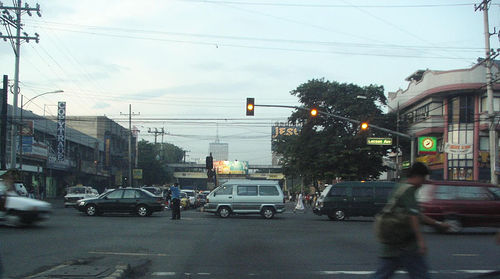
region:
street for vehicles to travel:
[22, 218, 492, 260]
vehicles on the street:
[60, 172, 499, 227]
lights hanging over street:
[238, 92, 379, 135]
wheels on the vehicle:
[87, 202, 153, 219]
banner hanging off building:
[440, 135, 476, 162]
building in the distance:
[200, 129, 235, 164]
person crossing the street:
[356, 155, 454, 277]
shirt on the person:
[384, 181, 424, 251]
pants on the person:
[375, 240, 432, 277]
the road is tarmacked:
[170, 241, 281, 266]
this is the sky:
[120, 56, 206, 82]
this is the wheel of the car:
[83, 200, 94, 215]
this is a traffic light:
[245, 100, 257, 115]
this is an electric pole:
[1, 1, 41, 97]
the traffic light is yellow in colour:
[246, 96, 253, 116]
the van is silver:
[198, 175, 288, 227]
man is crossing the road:
[373, 151, 455, 276]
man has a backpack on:
[373, 154, 445, 276]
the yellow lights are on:
[236, 87, 375, 142]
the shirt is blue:
[161, 178, 182, 204]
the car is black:
[72, 175, 163, 222]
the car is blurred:
[431, 177, 498, 227]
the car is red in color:
[428, 180, 498, 230]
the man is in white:
[296, 190, 307, 210]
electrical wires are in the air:
[36, 34, 283, 126]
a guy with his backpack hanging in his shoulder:
[376, 160, 433, 275]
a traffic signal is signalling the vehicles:
[239, 96, 418, 208]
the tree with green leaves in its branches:
[271, 64, 391, 209]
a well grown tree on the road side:
[207, 75, 389, 216]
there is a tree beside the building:
[275, 56, 499, 191]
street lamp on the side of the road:
[13, 85, 101, 217]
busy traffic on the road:
[0, 169, 491, 244]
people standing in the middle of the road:
[129, 169, 224, 256]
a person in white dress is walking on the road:
[284, 184, 320, 229]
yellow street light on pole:
[234, 93, 271, 124]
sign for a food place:
[415, 128, 440, 158]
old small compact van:
[203, 148, 285, 229]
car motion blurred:
[0, 180, 61, 237]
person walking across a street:
[380, 148, 452, 277]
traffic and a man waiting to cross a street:
[72, 163, 385, 228]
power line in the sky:
[119, 117, 243, 143]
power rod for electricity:
[483, 12, 496, 178]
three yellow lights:
[241, 92, 371, 133]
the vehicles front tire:
[218, 204, 231, 217]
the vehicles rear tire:
[262, 204, 277, 220]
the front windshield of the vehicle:
[321, 183, 330, 196]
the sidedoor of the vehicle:
[215, 184, 232, 209]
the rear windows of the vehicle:
[240, 184, 278, 198]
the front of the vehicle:
[202, 178, 237, 220]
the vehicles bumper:
[312, 204, 322, 214]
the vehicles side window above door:
[225, 176, 259, 197]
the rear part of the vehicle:
[252, 173, 290, 222]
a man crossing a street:
[360, 150, 462, 275]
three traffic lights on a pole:
[240, 90, 419, 157]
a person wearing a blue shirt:
[167, 185, 182, 197]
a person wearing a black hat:
[404, 158, 434, 181]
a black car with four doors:
[77, 184, 157, 220]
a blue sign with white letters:
[52, 96, 67, 160]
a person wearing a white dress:
[295, 188, 305, 211]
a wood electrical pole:
[119, 93, 142, 190]